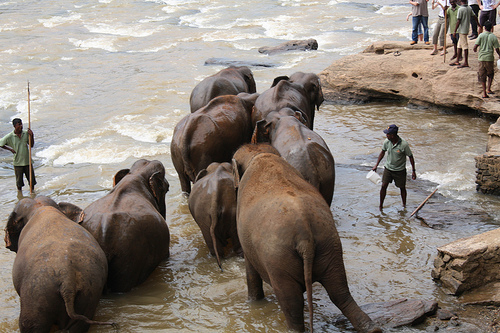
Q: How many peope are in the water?
A: Two.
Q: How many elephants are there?
A: Eight.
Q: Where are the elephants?
A: In the water.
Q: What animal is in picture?
A: Elephants.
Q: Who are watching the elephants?
A: People.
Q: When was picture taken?
A: Daytime.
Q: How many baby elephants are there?
A: One.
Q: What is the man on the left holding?
A: Long stick.